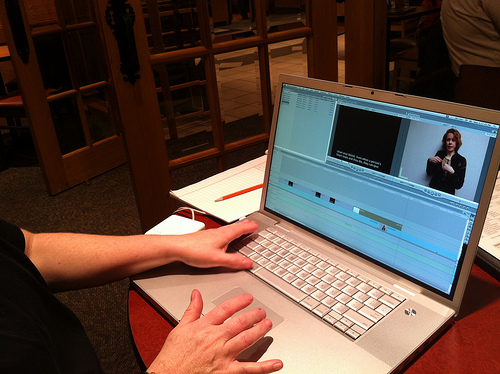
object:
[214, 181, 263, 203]
pencil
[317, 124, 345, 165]
ground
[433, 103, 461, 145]
ground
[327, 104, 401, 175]
black screen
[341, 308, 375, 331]
button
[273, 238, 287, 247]
button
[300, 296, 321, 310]
button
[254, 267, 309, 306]
button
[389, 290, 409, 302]
button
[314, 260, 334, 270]
button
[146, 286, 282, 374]
hand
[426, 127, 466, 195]
image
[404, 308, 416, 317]
stick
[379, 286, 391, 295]
silver button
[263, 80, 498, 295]
screen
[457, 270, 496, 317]
shadow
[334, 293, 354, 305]
button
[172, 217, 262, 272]
left hand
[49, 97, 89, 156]
glass pane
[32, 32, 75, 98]
glass pane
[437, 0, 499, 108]
man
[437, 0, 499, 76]
shirt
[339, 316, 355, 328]
button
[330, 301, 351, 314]
button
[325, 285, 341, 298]
button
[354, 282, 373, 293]
button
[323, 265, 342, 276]
button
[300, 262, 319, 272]
button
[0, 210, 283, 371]
person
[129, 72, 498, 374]
laptop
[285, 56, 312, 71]
tile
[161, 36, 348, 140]
floor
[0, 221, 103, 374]
black shirt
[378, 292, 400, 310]
button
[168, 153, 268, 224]
papers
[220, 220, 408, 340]
keyboard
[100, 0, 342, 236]
door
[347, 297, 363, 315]
button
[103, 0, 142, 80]
handle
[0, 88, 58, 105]
cushion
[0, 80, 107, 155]
chair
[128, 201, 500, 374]
table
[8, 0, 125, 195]
door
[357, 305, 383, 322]
button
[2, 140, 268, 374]
floor